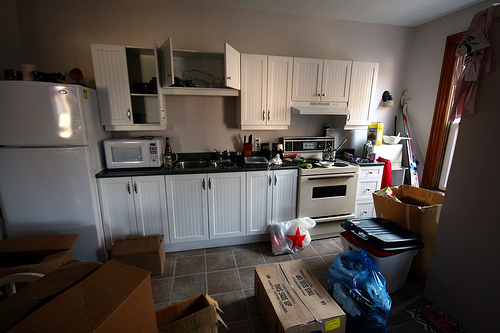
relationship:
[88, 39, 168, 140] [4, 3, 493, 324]
cupboard in kitchen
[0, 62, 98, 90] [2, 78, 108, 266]
stuff on fridge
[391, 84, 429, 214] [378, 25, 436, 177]
skiis on wall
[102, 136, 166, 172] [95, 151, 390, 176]
microwave on counter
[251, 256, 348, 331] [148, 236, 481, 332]
box on  the ground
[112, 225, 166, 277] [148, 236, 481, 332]
box on  the ground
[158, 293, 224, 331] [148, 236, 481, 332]
box on  the ground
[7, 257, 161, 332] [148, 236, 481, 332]
box on  the ground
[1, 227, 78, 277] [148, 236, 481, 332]
box on  the ground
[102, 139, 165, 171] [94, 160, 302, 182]
microwave on  the counter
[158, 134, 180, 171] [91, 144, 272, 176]
bottle on  the counter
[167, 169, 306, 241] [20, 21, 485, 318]
doors in a kitchen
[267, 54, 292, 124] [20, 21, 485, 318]
door in a kitchen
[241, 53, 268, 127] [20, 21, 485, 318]
door in a kitchen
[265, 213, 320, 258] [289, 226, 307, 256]
plastic bag with star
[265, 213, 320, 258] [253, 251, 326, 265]
plastic bag on ground